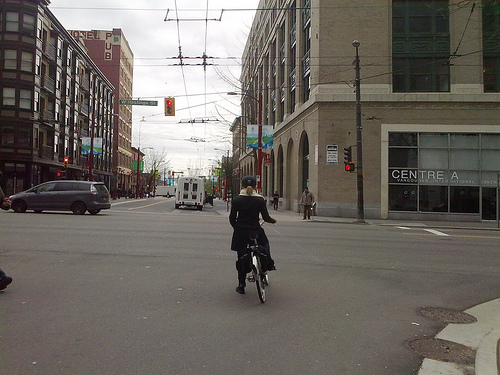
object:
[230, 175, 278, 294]
woman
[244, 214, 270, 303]
bike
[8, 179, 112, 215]
car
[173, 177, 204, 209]
bus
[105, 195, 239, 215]
street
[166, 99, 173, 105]
light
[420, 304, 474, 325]
cover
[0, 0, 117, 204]
building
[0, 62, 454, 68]
wire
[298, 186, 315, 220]
man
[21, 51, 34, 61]
window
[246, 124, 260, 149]
sign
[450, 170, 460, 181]
lettering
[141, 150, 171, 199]
tree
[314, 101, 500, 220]
wall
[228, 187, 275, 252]
jacket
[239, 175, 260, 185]
helmet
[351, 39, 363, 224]
pole